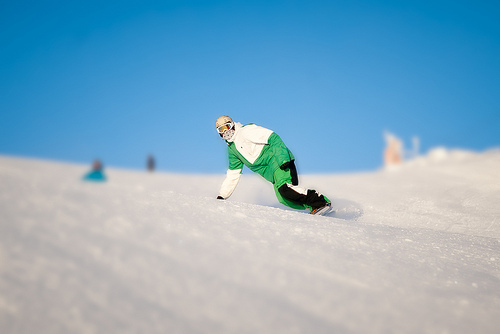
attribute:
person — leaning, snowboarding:
[216, 114, 332, 216]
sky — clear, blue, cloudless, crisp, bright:
[1, 0, 499, 176]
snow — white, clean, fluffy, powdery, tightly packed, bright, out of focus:
[0, 147, 499, 333]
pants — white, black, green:
[270, 164, 329, 213]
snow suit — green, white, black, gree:
[218, 121, 331, 211]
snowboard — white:
[307, 200, 331, 216]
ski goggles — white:
[216, 122, 235, 135]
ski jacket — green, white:
[220, 121, 296, 199]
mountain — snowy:
[0, 145, 499, 331]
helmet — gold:
[216, 116, 233, 131]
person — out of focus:
[80, 158, 107, 182]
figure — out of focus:
[146, 153, 157, 170]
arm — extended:
[216, 147, 243, 200]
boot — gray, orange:
[312, 197, 328, 216]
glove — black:
[280, 163, 291, 171]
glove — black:
[216, 195, 224, 200]